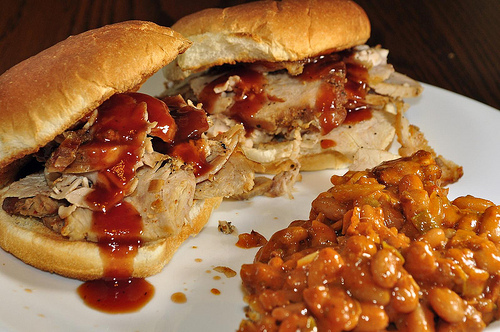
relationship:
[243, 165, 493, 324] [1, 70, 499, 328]
bean on plate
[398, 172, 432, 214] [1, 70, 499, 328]
bean on plate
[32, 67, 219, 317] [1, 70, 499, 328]
bbq on plate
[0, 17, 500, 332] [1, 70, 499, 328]
food on plate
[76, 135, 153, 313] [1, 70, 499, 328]
barbecue sauce on plate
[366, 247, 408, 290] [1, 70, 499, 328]
bean on plate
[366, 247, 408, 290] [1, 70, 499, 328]
bean piled plate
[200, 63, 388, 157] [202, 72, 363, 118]
sandwich has bbq pork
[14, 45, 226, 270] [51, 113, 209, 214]
sandwich has bbq pork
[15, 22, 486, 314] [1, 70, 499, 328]
food on plate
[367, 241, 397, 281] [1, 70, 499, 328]
bean on plate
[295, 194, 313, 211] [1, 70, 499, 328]
rice on plate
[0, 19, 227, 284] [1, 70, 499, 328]
sandwich on plate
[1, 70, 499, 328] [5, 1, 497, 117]
plate on table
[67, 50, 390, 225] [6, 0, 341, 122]
meat in between bread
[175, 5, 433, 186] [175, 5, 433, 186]
bun set on bun set